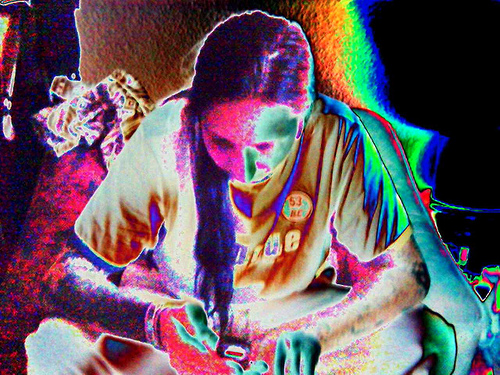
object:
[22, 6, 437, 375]
person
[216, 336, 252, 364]
cell phone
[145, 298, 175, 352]
wrist watch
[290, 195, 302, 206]
number 53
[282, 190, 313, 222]
circle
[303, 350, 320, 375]
fingers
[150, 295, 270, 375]
hand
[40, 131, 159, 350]
arm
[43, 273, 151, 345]
spots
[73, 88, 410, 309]
shirt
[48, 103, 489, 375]
chair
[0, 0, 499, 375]
image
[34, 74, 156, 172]
items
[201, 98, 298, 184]
face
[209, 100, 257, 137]
spot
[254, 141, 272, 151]
eye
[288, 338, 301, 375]
finger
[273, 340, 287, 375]
finger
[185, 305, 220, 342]
finger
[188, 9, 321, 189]
head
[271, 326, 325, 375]
hand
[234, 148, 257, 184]
nose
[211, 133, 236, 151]
eye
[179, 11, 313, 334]
hair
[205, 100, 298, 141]
forehead